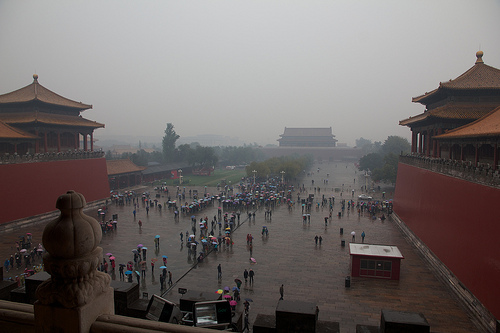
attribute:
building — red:
[347, 242, 404, 279]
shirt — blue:
[281, 282, 288, 302]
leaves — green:
[354, 131, 406, 178]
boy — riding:
[152, 232, 163, 252]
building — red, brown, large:
[387, 49, 498, 331]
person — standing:
[240, 267, 265, 286]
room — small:
[346, 243, 403, 283]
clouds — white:
[61, 22, 377, 109]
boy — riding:
[128, 171, 168, 201]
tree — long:
[158, 120, 180, 161]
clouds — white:
[6, 0, 498, 146]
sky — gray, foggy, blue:
[0, 4, 493, 154]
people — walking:
[10, 165, 400, 325]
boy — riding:
[119, 265, 138, 279]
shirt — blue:
[121, 263, 131, 279]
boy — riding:
[277, 282, 284, 299]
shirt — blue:
[142, 185, 153, 196]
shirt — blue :
[270, 280, 289, 296]